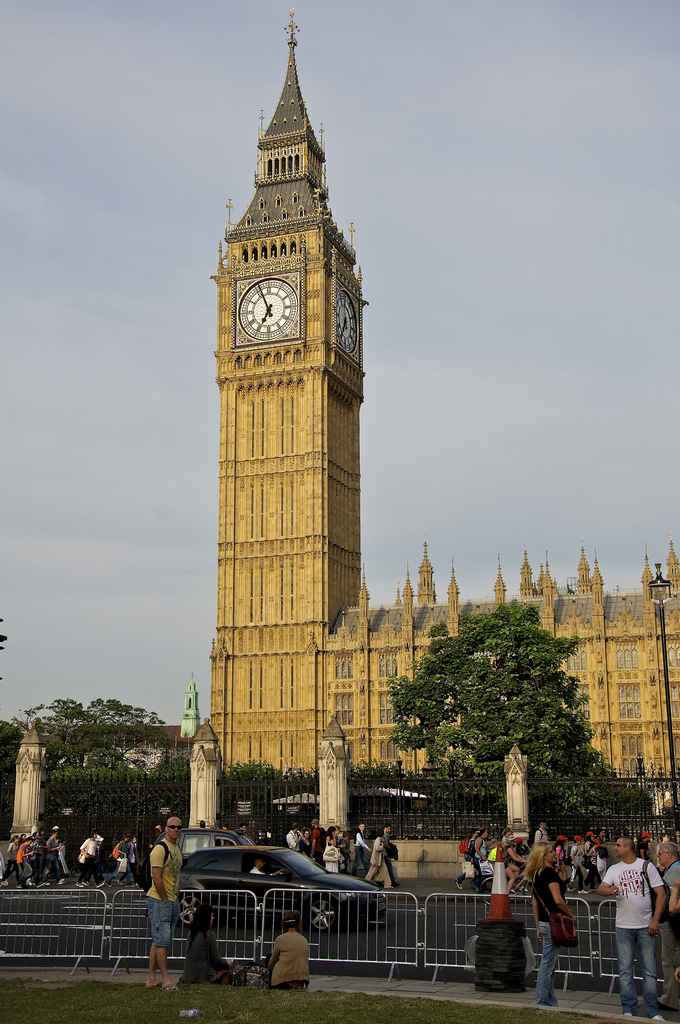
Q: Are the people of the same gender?
A: No, they are both male and female.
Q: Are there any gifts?
A: No, there are no gifts.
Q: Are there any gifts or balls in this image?
A: No, there are no gifts or balls.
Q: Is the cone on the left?
A: No, the cone is on the right of the image.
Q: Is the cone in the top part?
A: No, the cone is in the bottom of the image.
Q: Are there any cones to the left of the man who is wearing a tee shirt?
A: Yes, there is a cone to the left of the man.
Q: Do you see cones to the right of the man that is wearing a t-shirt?
A: No, the cone is to the left of the man.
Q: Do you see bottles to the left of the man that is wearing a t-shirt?
A: No, there is a cone to the left of the man.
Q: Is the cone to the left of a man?
A: Yes, the cone is to the left of a man.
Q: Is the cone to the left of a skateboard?
A: No, the cone is to the left of a man.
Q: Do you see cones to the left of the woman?
A: Yes, there is a cone to the left of the woman.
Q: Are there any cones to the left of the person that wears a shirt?
A: Yes, there is a cone to the left of the woman.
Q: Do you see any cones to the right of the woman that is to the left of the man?
A: No, the cone is to the left of the woman.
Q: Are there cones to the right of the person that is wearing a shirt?
A: No, the cone is to the left of the woman.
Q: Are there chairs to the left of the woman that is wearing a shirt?
A: No, there is a cone to the left of the woman.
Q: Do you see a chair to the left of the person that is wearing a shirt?
A: No, there is a cone to the left of the woman.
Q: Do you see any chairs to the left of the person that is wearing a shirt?
A: No, there is a cone to the left of the woman.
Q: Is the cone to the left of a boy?
A: No, the cone is to the left of a woman.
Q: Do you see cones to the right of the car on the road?
A: Yes, there is a cone to the right of the car.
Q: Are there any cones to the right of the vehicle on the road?
A: Yes, there is a cone to the right of the car.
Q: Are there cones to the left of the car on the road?
A: No, the cone is to the right of the car.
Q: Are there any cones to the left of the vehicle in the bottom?
A: No, the cone is to the right of the car.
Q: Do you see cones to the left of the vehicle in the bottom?
A: No, the cone is to the right of the car.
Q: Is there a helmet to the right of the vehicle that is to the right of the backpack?
A: No, there is a cone to the right of the car.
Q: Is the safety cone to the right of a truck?
A: No, the safety cone is to the right of the car.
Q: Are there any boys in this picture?
A: No, there are no boys.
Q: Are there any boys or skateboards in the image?
A: No, there are no boys or skateboards.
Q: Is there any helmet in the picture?
A: No, there are no helmets.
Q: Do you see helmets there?
A: No, there are no helmets.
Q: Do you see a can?
A: Yes, there is a can.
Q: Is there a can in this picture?
A: Yes, there is a can.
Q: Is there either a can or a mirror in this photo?
A: Yes, there is a can.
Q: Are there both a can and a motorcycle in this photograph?
A: No, there is a can but no motorcycles.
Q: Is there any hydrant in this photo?
A: No, there are no fire hydrants.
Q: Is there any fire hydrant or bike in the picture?
A: No, there are no fire hydrants or bikes.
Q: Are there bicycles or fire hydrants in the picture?
A: No, there are no fire hydrants or bicycles.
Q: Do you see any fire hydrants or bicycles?
A: No, there are no fire hydrants or bicycles.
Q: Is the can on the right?
A: Yes, the can is on the right of the image.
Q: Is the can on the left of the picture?
A: No, the can is on the right of the image.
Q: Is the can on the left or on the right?
A: The can is on the right of the image.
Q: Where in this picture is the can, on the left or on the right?
A: The can is on the right of the image.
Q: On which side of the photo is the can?
A: The can is on the right of the image.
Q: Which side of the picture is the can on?
A: The can is on the right of the image.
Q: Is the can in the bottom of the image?
A: Yes, the can is in the bottom of the image.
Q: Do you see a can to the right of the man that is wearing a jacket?
A: Yes, there is a can to the right of the man.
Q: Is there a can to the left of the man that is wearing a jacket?
A: No, the can is to the right of the man.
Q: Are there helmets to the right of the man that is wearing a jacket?
A: No, there is a can to the right of the man.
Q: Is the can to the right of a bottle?
A: No, the can is to the right of the man.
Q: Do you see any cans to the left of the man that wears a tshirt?
A: Yes, there is a can to the left of the man.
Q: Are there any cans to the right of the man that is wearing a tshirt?
A: No, the can is to the left of the man.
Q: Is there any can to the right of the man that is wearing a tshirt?
A: No, the can is to the left of the man.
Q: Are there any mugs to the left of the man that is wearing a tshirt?
A: No, there is a can to the left of the man.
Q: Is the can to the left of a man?
A: Yes, the can is to the left of a man.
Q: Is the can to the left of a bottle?
A: No, the can is to the left of a man.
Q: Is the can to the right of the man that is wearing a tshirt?
A: No, the can is to the left of the man.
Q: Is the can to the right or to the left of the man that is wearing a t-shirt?
A: The can is to the left of the man.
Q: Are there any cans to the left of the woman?
A: Yes, there is a can to the left of the woman.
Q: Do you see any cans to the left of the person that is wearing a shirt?
A: Yes, there is a can to the left of the woman.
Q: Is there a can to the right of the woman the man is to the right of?
A: No, the can is to the left of the woman.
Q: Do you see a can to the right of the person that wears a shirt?
A: No, the can is to the left of the woman.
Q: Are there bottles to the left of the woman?
A: No, there is a can to the left of the woman.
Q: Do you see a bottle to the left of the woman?
A: No, there is a can to the left of the woman.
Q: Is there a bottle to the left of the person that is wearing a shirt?
A: No, there is a can to the left of the woman.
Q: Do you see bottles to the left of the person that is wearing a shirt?
A: No, there is a can to the left of the woman.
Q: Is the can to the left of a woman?
A: Yes, the can is to the left of a woman.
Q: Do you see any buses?
A: No, there are no buses.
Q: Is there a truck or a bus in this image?
A: No, there are no buses or trucks.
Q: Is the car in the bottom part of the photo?
A: Yes, the car is in the bottom of the image.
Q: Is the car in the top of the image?
A: No, the car is in the bottom of the image.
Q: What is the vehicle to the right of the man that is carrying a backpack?
A: The vehicle is a car.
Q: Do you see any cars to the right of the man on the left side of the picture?
A: Yes, there is a car to the right of the man.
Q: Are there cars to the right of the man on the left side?
A: Yes, there is a car to the right of the man.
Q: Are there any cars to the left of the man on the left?
A: No, the car is to the right of the man.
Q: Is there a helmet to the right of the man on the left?
A: No, there is a car to the right of the man.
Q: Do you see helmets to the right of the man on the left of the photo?
A: No, there is a car to the right of the man.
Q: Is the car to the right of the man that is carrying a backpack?
A: Yes, the car is to the right of the man.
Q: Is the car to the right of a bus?
A: No, the car is to the right of the man.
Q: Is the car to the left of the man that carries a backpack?
A: No, the car is to the right of the man.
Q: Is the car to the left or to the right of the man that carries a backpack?
A: The car is to the right of the man.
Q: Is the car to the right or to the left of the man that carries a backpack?
A: The car is to the right of the man.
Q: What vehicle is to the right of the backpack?
A: The vehicle is a car.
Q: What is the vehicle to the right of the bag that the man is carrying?
A: The vehicle is a car.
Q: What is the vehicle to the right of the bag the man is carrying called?
A: The vehicle is a car.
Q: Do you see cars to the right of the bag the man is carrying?
A: Yes, there is a car to the right of the backpack.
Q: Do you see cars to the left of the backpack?
A: No, the car is to the right of the backpack.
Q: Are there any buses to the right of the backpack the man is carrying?
A: No, there is a car to the right of the backpack.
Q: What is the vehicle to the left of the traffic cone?
A: The vehicle is a car.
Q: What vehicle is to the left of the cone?
A: The vehicle is a car.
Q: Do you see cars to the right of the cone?
A: No, the car is to the left of the cone.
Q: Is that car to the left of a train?
A: No, the car is to the left of the cone.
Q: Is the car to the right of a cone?
A: No, the car is to the left of a cone.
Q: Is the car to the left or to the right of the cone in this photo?
A: The car is to the left of the cone.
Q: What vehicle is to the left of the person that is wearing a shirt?
A: The vehicle is a car.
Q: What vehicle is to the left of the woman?
A: The vehicle is a car.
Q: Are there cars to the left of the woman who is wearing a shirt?
A: Yes, there is a car to the left of the woman.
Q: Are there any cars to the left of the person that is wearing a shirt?
A: Yes, there is a car to the left of the woman.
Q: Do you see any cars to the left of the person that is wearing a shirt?
A: Yes, there is a car to the left of the woman.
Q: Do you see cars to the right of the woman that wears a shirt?
A: No, the car is to the left of the woman.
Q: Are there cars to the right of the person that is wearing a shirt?
A: No, the car is to the left of the woman.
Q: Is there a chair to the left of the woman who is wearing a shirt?
A: No, there is a car to the left of the woman.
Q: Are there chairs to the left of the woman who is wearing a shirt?
A: No, there is a car to the left of the woman.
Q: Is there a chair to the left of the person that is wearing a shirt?
A: No, there is a car to the left of the woman.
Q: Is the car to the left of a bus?
A: No, the car is to the left of the woman.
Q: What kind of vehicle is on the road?
A: The vehicle is a car.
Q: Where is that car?
A: The car is on the road.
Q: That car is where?
A: The car is on the road.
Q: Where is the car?
A: The car is on the road.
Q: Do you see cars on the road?
A: Yes, there is a car on the road.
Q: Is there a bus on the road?
A: No, there is a car on the road.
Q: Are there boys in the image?
A: No, there are no boys.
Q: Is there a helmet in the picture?
A: No, there are no helmets.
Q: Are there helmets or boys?
A: No, there are no helmets or boys.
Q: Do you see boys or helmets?
A: No, there are no helmets or boys.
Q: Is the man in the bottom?
A: Yes, the man is in the bottom of the image.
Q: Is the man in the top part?
A: No, the man is in the bottom of the image.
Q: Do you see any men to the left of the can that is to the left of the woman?
A: Yes, there is a man to the left of the can.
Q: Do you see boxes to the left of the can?
A: No, there is a man to the left of the can.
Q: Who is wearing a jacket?
A: The man is wearing a jacket.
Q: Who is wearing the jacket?
A: The man is wearing a jacket.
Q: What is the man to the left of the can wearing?
A: The man is wearing a jacket.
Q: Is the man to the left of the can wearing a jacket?
A: Yes, the man is wearing a jacket.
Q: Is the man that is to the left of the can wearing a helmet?
A: No, the man is wearing a jacket.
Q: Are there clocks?
A: Yes, there is a clock.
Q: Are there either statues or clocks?
A: Yes, there is a clock.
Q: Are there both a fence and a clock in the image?
A: Yes, there are both a clock and a fence.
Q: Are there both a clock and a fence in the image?
A: Yes, there are both a clock and a fence.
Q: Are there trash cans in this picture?
A: No, there are no trash cans.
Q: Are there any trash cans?
A: No, there are no trash cans.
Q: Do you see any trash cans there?
A: No, there are no trash cans.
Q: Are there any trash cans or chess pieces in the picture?
A: No, there are no trash cans or chess pieces.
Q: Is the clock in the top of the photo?
A: Yes, the clock is in the top of the image.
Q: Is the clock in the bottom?
A: No, the clock is in the top of the image.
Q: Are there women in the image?
A: Yes, there is a woman.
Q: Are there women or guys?
A: Yes, there is a woman.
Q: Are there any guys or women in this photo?
A: Yes, there is a woman.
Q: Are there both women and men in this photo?
A: Yes, there are both a woman and a man.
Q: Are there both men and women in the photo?
A: Yes, there are both a woman and a man.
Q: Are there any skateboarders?
A: No, there are no skateboarders.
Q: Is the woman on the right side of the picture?
A: Yes, the woman is on the right of the image.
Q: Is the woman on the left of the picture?
A: No, the woman is on the right of the image.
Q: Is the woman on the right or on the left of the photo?
A: The woman is on the right of the image.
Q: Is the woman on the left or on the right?
A: The woman is on the right of the image.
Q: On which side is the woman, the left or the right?
A: The woman is on the right of the image.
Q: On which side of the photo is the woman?
A: The woman is on the right of the image.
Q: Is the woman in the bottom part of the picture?
A: Yes, the woman is in the bottom of the image.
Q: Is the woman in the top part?
A: No, the woman is in the bottom of the image.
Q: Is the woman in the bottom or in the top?
A: The woman is in the bottom of the image.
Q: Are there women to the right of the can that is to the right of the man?
A: Yes, there is a woman to the right of the can.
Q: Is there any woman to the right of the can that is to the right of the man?
A: Yes, there is a woman to the right of the can.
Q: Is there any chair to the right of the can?
A: No, there is a woman to the right of the can.